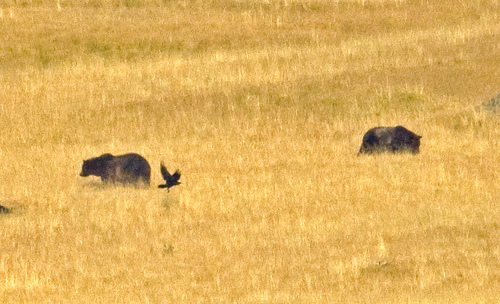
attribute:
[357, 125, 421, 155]
bear — black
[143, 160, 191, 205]
bird — small , black 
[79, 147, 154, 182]
bear — large, black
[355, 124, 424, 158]
bear — walking 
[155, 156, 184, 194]
bird — black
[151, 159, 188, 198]
raptor — black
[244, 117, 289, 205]
dry field — yellow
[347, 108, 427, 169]
bear — black, large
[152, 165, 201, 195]
bird — flying 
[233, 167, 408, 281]
grass — brown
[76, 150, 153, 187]
bear — walking 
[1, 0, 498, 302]
field — yellow, dry, large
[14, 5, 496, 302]
grass — dry, yellow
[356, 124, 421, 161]
bear — dark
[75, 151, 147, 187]
bear — large, black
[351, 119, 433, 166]
bear — black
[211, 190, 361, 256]
grass — yellow, dry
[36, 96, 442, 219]
creatures — three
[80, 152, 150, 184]
bear — black, large, walking 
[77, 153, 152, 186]
bison — grazing 